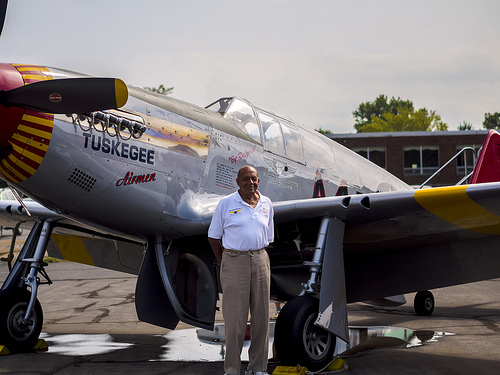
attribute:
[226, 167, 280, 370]
man — standing, wearing, bald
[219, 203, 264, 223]
design — yellow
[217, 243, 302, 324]
pants — tan, worn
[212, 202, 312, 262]
shirt — white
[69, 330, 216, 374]
puddle — large, water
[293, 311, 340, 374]
wheels — silver, black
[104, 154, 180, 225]
print — red, blue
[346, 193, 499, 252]
wing — gray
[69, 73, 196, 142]
propeller — yellow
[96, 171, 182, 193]
writing — red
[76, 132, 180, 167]
lettering — dark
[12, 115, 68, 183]
stripes — red, yellow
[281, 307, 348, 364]
tire — black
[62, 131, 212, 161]
words — black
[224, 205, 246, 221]
logo — blue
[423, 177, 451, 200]
paint — yellow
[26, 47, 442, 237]
plane — vintage, behind, old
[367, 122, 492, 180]
building — brown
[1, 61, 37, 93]
nose — red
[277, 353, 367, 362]
brake — yellow